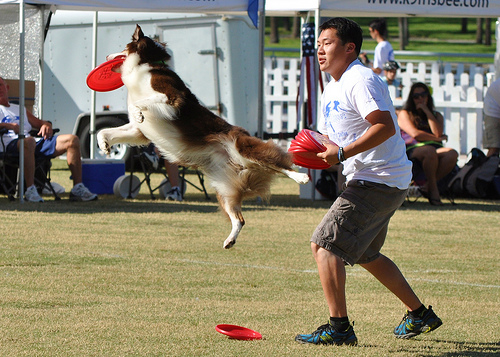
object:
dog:
[94, 24, 310, 249]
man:
[292, 16, 442, 346]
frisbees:
[285, 125, 335, 170]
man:
[0, 76, 97, 204]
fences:
[265, 61, 500, 166]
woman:
[396, 81, 458, 207]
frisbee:
[213, 321, 262, 343]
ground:
[0, 159, 499, 356]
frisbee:
[83, 57, 131, 92]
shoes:
[294, 322, 359, 349]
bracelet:
[336, 145, 344, 164]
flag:
[294, 16, 323, 187]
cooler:
[78, 159, 126, 196]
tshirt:
[316, 60, 412, 191]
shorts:
[307, 179, 407, 267]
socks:
[327, 316, 353, 331]